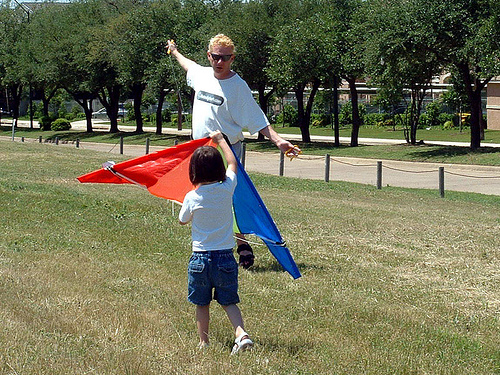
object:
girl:
[176, 129, 255, 358]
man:
[164, 33, 302, 271]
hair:
[208, 32, 234, 55]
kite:
[70, 120, 190, 222]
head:
[207, 32, 234, 74]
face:
[207, 44, 233, 75]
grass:
[2, 195, 103, 260]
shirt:
[179, 170, 237, 253]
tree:
[325, 22, 457, 168]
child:
[178, 129, 257, 361]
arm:
[237, 81, 283, 144]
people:
[165, 33, 302, 357]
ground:
[64, 239, 164, 332]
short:
[185, 249, 240, 305]